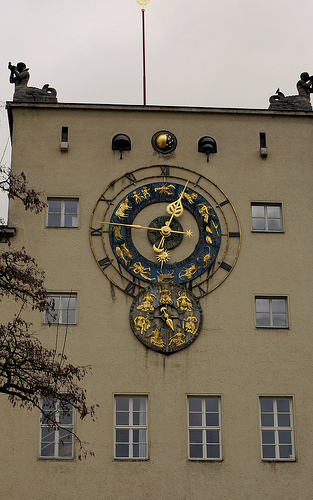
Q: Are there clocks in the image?
A: Yes, there is a clock.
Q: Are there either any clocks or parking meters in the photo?
A: Yes, there is a clock.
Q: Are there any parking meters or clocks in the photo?
A: Yes, there is a clock.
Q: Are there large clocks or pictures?
A: Yes, there is a large clock.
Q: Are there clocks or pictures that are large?
A: Yes, the clock is large.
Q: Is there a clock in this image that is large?
A: Yes, there is a large clock.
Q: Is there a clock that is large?
A: Yes, there is a clock that is large.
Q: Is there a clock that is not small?
A: Yes, there is a large clock.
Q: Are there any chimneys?
A: No, there are no chimneys.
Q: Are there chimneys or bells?
A: No, there are no chimneys or bells.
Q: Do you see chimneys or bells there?
A: No, there are no chimneys or bells.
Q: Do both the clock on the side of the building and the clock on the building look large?
A: Yes, both the clock and the clock are large.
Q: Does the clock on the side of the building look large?
A: Yes, the clock is large.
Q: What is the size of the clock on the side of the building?
A: The clock is large.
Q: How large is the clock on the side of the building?
A: The clock is large.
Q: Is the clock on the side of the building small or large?
A: The clock is large.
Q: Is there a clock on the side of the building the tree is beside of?
A: Yes, there is a clock on the side of the building.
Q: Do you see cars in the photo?
A: No, there are no cars.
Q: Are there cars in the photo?
A: No, there are no cars.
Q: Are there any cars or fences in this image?
A: No, there are no cars or fences.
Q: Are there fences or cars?
A: No, there are no cars or fences.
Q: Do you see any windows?
A: Yes, there is a window.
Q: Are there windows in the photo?
A: Yes, there is a window.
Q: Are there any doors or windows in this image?
A: Yes, there is a window.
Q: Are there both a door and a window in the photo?
A: No, there is a window but no doors.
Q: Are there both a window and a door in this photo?
A: No, there is a window but no doors.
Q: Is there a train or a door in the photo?
A: No, there are no doors or trains.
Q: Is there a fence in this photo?
A: No, there are no fences.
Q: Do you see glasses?
A: No, there are no glasses.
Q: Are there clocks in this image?
A: Yes, there is a clock.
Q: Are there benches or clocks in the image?
A: Yes, there is a clock.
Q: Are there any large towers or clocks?
A: Yes, there is a large clock.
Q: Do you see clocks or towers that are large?
A: Yes, the clock is large.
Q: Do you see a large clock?
A: Yes, there is a large clock.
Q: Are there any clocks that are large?
A: Yes, there is a clock that is large.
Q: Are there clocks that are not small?
A: Yes, there is a large clock.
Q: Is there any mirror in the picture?
A: No, there are no mirrors.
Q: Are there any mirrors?
A: No, there are no mirrors.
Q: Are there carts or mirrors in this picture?
A: No, there are no mirrors or carts.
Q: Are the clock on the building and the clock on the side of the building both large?
A: Yes, both the clock and the clock are large.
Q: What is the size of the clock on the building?
A: The clock is large.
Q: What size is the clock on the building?
A: The clock is large.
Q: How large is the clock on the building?
A: The clock is large.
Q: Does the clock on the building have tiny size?
A: No, the clock is large.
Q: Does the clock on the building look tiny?
A: No, the clock is large.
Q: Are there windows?
A: Yes, there is a window.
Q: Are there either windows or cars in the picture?
A: Yes, there is a window.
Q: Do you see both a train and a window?
A: No, there is a window but no trains.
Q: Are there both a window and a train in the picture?
A: No, there is a window but no trains.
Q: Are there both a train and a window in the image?
A: No, there is a window but no trains.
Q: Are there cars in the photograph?
A: No, there are no cars.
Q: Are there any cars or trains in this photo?
A: No, there are no cars or trains.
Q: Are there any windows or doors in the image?
A: Yes, there is a window.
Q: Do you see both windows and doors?
A: No, there is a window but no doors.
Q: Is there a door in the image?
A: No, there are no doors.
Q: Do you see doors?
A: No, there are no doors.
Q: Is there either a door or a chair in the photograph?
A: No, there are no doors or chairs.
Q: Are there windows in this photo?
A: Yes, there is a window.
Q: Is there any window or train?
A: Yes, there is a window.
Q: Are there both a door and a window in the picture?
A: No, there is a window but no doors.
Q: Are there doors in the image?
A: No, there are no doors.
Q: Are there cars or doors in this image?
A: No, there are no doors or cars.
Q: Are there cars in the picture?
A: No, there are no cars.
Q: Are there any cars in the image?
A: No, there are no cars.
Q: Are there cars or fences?
A: No, there are no cars or fences.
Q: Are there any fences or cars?
A: No, there are no cars or fences.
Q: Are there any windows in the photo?
A: Yes, there is a window.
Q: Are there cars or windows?
A: Yes, there is a window.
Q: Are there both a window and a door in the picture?
A: No, there is a window but no doors.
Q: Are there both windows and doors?
A: No, there is a window but no doors.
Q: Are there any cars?
A: No, there are no cars.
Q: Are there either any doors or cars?
A: No, there are no cars or doors.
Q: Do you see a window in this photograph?
A: Yes, there is a window.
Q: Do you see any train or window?
A: Yes, there is a window.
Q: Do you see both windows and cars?
A: No, there is a window but no cars.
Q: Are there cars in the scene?
A: No, there are no cars.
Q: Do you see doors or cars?
A: No, there are no cars or doors.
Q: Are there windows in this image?
A: Yes, there is a window.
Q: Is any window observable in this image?
A: Yes, there is a window.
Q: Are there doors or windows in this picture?
A: Yes, there is a window.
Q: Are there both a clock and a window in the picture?
A: Yes, there are both a window and a clock.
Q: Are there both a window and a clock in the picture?
A: Yes, there are both a window and a clock.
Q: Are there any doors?
A: No, there are no doors.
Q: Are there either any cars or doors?
A: No, there are no doors or cars.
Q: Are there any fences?
A: No, there are no fences.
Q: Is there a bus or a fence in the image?
A: No, there are no fences or buses.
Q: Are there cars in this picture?
A: No, there are no cars.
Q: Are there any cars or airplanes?
A: No, there are no cars or airplanes.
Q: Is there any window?
A: Yes, there is a window.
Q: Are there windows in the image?
A: Yes, there is a window.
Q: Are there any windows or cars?
A: Yes, there is a window.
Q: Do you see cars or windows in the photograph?
A: Yes, there is a window.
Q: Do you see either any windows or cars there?
A: Yes, there is a window.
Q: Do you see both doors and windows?
A: No, there is a window but no doors.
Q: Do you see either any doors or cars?
A: No, there are no doors or cars.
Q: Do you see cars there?
A: No, there are no cars.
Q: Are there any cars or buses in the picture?
A: No, there are no cars or buses.